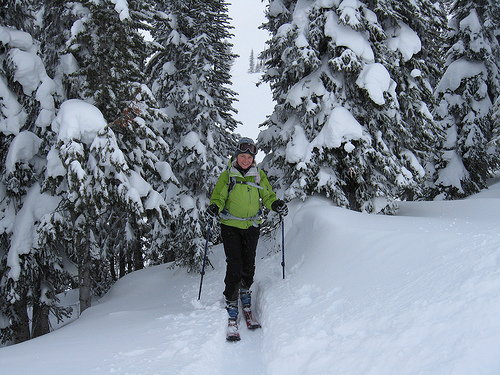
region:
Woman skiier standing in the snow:
[179, 133, 304, 357]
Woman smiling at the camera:
[174, 126, 304, 356]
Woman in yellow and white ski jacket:
[189, 142, 282, 249]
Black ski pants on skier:
[212, 217, 275, 309]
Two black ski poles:
[182, 203, 310, 307]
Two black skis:
[219, 285, 271, 355]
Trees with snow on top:
[4, 3, 497, 355]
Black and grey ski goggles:
[229, 134, 268, 174]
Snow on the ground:
[1, 188, 494, 373]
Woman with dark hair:
[179, 133, 323, 356]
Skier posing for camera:
[194, 135, 291, 345]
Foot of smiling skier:
[221, 310, 243, 347]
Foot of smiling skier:
[239, 304, 264, 330]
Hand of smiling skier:
[203, 204, 225, 222]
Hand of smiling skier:
[271, 201, 291, 216]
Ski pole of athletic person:
[274, 214, 293, 284]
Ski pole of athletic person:
[197, 240, 208, 305]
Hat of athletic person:
[232, 140, 260, 157]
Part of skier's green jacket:
[234, 192, 254, 208]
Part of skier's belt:
[224, 214, 262, 222]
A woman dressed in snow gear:
[198, 136, 286, 341]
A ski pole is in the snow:
[196, 218, 215, 305]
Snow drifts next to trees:
[287, 190, 492, 247]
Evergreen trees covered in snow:
[270, 4, 494, 190]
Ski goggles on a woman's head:
[233, 139, 258, 154]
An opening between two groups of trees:
[227, 0, 272, 140]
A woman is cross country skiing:
[196, 136, 288, 343]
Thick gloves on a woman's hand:
[271, 198, 291, 215]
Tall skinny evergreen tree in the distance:
[246, 48, 256, 77]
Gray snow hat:
[232, 137, 257, 158]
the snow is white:
[347, 234, 465, 348]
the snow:
[318, 253, 453, 346]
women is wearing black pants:
[220, 225, 263, 292]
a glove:
[270, 198, 290, 218]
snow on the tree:
[17, 105, 129, 186]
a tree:
[240, 45, 258, 74]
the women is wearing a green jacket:
[215, 180, 266, 216]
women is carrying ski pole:
[202, 235, 210, 276]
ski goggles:
[237, 143, 257, 153]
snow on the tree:
[315, 107, 367, 147]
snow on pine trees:
[278, 1, 495, 206]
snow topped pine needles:
[391, 101, 436, 153]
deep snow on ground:
[31, 203, 494, 370]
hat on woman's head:
[235, 138, 259, 158]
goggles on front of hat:
[238, 142, 256, 155]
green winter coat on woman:
[210, 166, 279, 229]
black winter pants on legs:
[221, 223, 259, 300]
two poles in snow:
[197, 202, 288, 301]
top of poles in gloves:
[204, 199, 291, 221]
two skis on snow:
[226, 309, 261, 341]